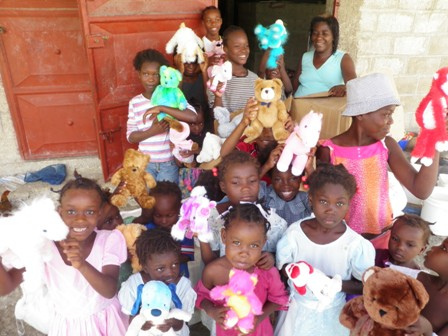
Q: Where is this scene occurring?
A: Outside a building.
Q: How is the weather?
A: Warm and dry.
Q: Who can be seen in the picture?
A: 16 kids.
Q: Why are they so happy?
A: They all just got new stuffed animals.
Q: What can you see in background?
A: Double doors.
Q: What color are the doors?
A: Light cherry.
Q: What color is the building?
A: White.